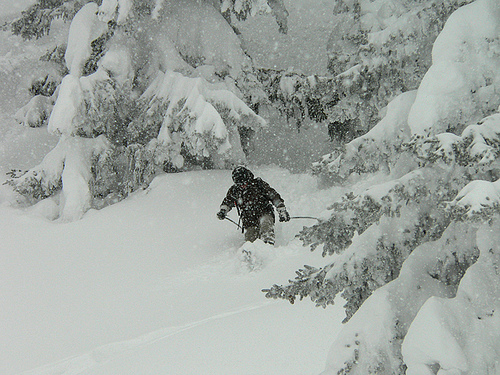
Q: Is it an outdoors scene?
A: Yes, it is outdoors.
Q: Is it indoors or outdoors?
A: It is outdoors.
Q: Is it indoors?
A: No, it is outdoors.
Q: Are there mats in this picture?
A: No, there are no mats.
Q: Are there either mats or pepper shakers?
A: No, there are no mats or pepper shakers.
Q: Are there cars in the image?
A: No, there are no cars.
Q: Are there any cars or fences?
A: No, there are no cars or fences.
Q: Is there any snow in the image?
A: Yes, there is snow.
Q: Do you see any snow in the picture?
A: Yes, there is snow.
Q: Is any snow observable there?
A: Yes, there is snow.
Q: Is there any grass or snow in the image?
A: Yes, there is snow.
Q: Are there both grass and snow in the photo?
A: No, there is snow but no grass.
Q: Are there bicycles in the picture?
A: No, there are no bicycles.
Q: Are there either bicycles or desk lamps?
A: No, there are no bicycles or desk lamps.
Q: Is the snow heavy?
A: Yes, the snow is heavy.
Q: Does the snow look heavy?
A: Yes, the snow is heavy.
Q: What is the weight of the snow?
A: The snow is heavy.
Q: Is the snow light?
A: No, the snow is heavy.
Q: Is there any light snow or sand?
A: No, there is snow but it is heavy.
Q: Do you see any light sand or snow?
A: No, there is snow but it is heavy.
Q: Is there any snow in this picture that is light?
A: No, there is snow but it is heavy.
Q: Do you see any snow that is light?
A: No, there is snow but it is heavy.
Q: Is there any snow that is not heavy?
A: No, there is snow but it is heavy.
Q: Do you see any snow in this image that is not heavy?
A: No, there is snow but it is heavy.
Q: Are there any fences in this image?
A: No, there are no fences.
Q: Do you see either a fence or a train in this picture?
A: No, there are no fences or trains.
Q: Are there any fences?
A: No, there are no fences.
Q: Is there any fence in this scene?
A: No, there are no fences.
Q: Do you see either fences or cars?
A: No, there are no fences or cars.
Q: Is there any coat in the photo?
A: Yes, there is a coat.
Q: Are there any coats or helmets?
A: Yes, there is a coat.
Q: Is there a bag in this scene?
A: No, there are no bags.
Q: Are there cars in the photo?
A: No, there are no cars.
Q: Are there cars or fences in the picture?
A: No, there are no cars or fences.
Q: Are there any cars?
A: No, there are no cars.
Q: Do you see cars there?
A: No, there are no cars.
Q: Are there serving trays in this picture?
A: No, there are no serving trays.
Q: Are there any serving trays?
A: No, there are no serving trays.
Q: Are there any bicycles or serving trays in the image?
A: No, there are no serving trays or bicycles.